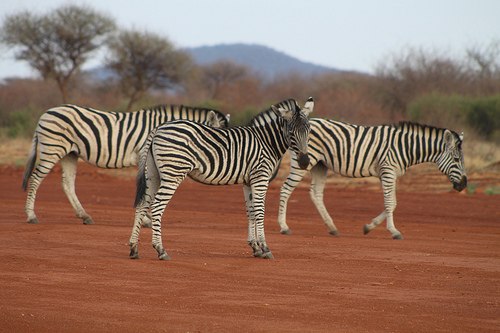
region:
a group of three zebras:
[13, 86, 478, 271]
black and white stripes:
[333, 124, 388, 169]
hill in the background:
[81, 28, 352, 95]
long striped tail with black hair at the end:
[121, 122, 160, 204]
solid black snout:
[452, 173, 470, 195]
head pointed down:
[409, 116, 476, 196]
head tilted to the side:
[263, 95, 323, 173]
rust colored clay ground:
[1, 164, 498, 331]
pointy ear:
[304, 95, 314, 116]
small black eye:
[451, 153, 459, 165]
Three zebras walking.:
[19, 94, 475, 274]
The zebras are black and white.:
[17, 92, 467, 282]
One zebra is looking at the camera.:
[19, 90, 477, 279]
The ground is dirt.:
[182, 263, 487, 329]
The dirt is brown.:
[216, 263, 474, 325]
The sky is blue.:
[310, 2, 462, 32]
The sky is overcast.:
[309, 4, 452, 38]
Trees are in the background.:
[1, 0, 187, 97]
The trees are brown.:
[2, 3, 193, 98]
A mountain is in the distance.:
[44, 15, 386, 97]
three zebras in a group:
[11, 34, 479, 271]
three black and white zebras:
[29, 60, 497, 274]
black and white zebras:
[12, 57, 494, 305]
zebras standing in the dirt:
[23, 22, 499, 291]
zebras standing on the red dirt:
[22, 40, 497, 313]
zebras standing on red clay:
[8, 16, 482, 302]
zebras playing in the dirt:
[23, 31, 493, 328]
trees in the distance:
[7, 6, 231, 131]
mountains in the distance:
[78, 5, 357, 130]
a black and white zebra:
[32, 32, 492, 255]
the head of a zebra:
[266, 91, 320, 171]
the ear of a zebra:
[301, 92, 320, 116]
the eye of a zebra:
[451, 152, 463, 165]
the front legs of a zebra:
[240, 177, 275, 249]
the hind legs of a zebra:
[124, 172, 183, 247]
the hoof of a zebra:
[154, 247, 174, 262]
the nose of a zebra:
[295, 150, 315, 170]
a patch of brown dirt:
[1, 157, 498, 331]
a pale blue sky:
[1, 0, 499, 82]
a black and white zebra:
[117, 90, 325, 266]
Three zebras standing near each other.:
[15, 95, 475, 261]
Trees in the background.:
[6, 5, 246, 106]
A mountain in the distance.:
[92, 30, 372, 83]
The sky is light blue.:
[211, 8, 434, 34]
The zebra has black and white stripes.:
[173, 128, 259, 158]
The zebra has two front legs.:
[240, 153, 281, 270]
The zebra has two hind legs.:
[117, 170, 198, 265]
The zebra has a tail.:
[127, 125, 164, 215]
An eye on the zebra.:
[450, 154, 466, 169]